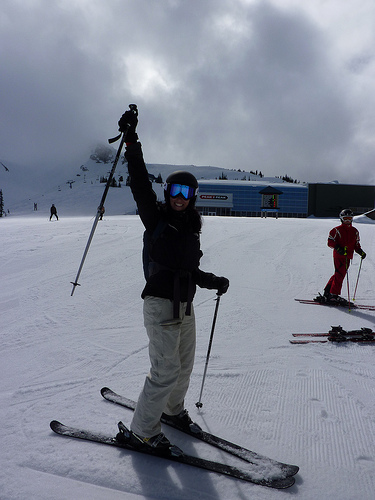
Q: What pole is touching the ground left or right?
A: Right.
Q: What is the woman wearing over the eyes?
A: Goggles.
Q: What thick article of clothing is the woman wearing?
A: Coat.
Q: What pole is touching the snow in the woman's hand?
A: Right.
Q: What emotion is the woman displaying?
A: Happiness.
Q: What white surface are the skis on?
A: Snow.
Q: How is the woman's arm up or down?
A: Up.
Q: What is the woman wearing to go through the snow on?
A: Skis.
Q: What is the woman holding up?
A: Ski pole.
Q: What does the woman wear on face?
A: Goggles.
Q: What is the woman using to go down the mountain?
A: Skis.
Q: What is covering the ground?
A: Snow.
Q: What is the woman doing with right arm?
A: Holding it up.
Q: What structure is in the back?
A: Building.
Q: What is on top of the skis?
A: Feet.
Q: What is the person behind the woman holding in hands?
A: Ski poles.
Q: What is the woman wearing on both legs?
A: Pants.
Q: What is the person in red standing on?
A: Skis.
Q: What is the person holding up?
A: A ski pole.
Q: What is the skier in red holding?
A: Ski poles.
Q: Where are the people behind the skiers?
A: In the distance.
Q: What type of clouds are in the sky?
A: Dark and cloudy.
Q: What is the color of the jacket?
A: Black.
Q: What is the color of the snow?
A: White.